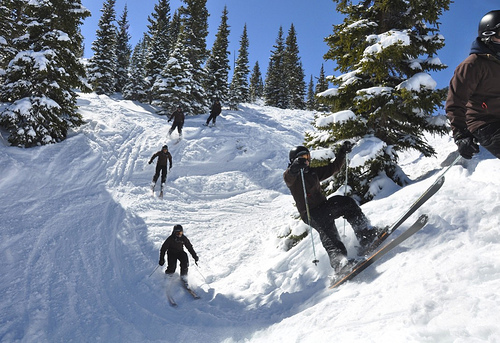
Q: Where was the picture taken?
A: At a ski slope.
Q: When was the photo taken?
A: During the day.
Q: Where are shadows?
A: On the snow.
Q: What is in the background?
A: Trees.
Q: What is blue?
A: Sky.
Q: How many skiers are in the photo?
A: Five.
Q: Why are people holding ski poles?
A: To ski.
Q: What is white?
A: Snow.